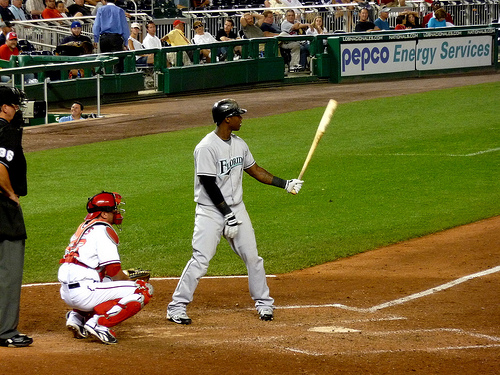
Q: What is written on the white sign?
A: Pepco Energy Services.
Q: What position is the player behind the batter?
A: Catcher.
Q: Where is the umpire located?
A: Behind the catcher.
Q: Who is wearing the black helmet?
A: The batter.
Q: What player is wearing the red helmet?
A: Catcher.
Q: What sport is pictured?
A: Baseball.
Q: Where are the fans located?
A: Behind the batter.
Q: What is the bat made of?
A: Wood.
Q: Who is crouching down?
A: Baseball catcher.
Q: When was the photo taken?
A: During baseball game.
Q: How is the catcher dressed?
A: In red and white uniform.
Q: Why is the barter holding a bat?
A: To hit ball.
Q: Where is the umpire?
A: Behind catcher.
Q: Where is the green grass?
A: Stadium.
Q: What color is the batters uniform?
A: Grey and black.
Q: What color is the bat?
A: Yellow.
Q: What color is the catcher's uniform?
A: Red and white.